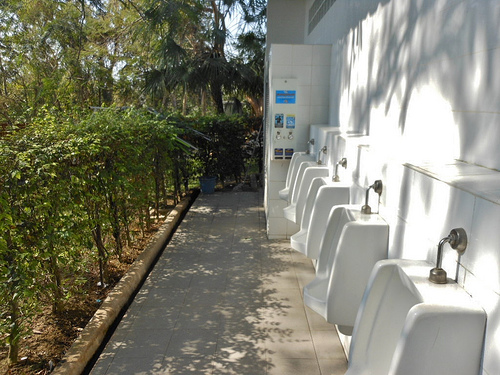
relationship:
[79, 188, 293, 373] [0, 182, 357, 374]
shadow on ground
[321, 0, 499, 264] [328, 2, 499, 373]
shadow on wall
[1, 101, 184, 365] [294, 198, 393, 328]
trees are beside urinal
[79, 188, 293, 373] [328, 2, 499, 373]
shadow on wall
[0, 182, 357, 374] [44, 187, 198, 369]
ground has curb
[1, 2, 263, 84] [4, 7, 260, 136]
sky through trees